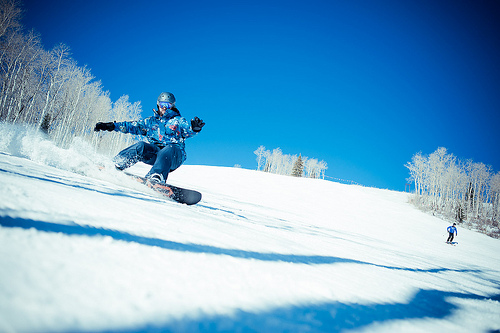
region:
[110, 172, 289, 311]
a ground covered in snow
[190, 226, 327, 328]
a ground covered in white snow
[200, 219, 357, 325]
snow covering the ground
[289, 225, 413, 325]
white snow covering the ground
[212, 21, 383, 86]
a sky that is blue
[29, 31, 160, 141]
snow on the trees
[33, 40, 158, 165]
white snow on the tree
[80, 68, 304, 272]
a person that is snowboarding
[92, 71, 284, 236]
a person wearing black gloves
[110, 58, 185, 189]
a persno wearing a helmet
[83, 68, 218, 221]
person snowboarding down a slope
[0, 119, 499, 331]
ground is covered in white snow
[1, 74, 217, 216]
snow being kicked up from the snowboarder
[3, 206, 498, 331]
shadows on the ground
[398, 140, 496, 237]
several white trees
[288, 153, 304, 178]
pine tree in the distance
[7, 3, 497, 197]
no clouds visible in the sky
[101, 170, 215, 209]
snowboard is tilted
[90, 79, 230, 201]
snowboarder is leaning back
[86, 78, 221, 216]
person snowboarding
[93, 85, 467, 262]
two people on the snow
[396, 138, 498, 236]
white trees on the slope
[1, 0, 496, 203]
bright blue sky with no clouds in sight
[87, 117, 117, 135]
black glove on the hand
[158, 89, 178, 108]
helmet on the head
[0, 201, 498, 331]
shadows on the ground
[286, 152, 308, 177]
pine tree in the distance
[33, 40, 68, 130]
tall snow covered tree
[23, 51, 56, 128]
tall snow covered tree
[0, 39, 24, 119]
tall snow covered tree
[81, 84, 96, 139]
tall snow covered tree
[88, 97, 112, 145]
tall snow covered tree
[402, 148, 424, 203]
tall snow covered tree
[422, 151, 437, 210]
tall snow covered tree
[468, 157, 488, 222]
tall snow covered tree